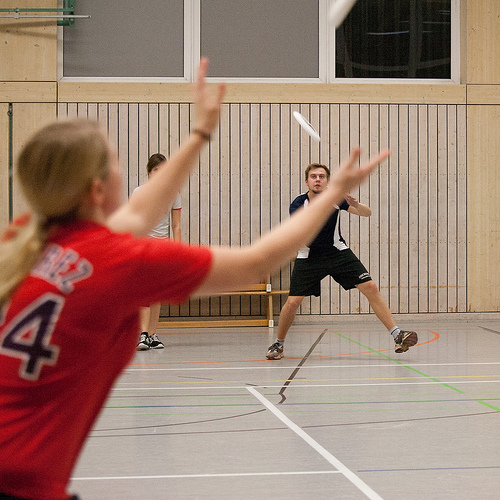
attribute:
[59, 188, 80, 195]
hair — blonde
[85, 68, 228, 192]
woman — raised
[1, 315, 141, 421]
shirt — red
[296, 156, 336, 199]
man — looking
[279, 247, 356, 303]
short — black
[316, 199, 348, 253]
top — dark, red, black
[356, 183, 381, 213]
bicept — part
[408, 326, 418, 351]
shoe — sole, black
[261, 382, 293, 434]
line — white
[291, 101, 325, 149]
dish — white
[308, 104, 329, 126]
frisbee — white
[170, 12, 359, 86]
window — up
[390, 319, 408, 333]
sock — white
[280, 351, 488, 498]
court — grey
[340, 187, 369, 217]
band — wrist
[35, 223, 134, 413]
jersey — red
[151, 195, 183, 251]
shirt — white